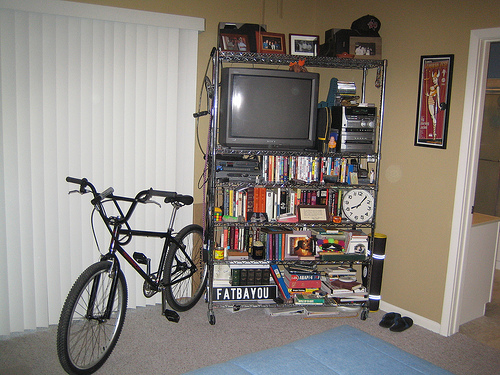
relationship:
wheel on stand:
[358, 308, 367, 320] [199, 48, 389, 320]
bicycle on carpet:
[55, 176, 212, 373] [2, 287, 499, 373]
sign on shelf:
[207, 280, 283, 308] [198, 65, 428, 317]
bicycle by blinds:
[55, 176, 212, 373] [1, 1, 205, 333]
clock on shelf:
[340, 189, 373, 223] [210, 219, 374, 227]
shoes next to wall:
[379, 307, 414, 330] [373, 5, 459, 335]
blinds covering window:
[1, 1, 205, 333] [1, 7, 199, 337]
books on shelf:
[210, 155, 380, 300] [198, 56, 388, 321]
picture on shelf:
[253, 30, 285, 57] [213, 48, 391, 73]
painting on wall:
[412, 53, 455, 149] [316, 0, 498, 336]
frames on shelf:
[214, 19, 385, 62] [215, 47, 383, 69]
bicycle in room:
[59, 176, 213, 374] [3, 1, 494, 372]